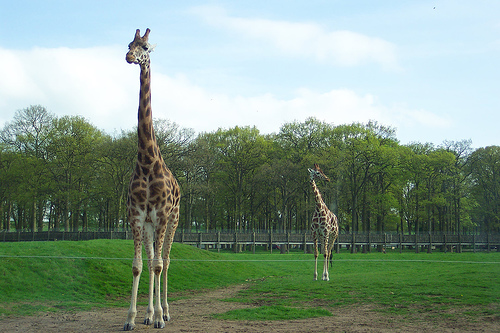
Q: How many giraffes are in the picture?
A: 2.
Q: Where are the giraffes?
A: On a field.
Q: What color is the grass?
A: Green.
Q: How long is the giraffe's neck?
A: Very long.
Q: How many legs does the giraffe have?
A: 4.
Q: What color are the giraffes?
A: Brown and tan.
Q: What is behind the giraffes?
A: Trees.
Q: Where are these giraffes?
A: In an enclosure.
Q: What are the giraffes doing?
A: Standing.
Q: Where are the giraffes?
A: In a park.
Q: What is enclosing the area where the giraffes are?
A: A fence.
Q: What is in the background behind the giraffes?
A: Trees.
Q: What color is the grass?
A: Green.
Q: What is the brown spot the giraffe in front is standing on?
A: Dirt patch.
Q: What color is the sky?
A: Blue and white.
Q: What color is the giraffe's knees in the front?
A: Brown.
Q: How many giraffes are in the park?
A: 2.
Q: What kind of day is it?
A: Sunny.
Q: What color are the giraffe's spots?
A: Brown and Tan.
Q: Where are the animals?
A: Grass field.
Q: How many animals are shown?
A: 2.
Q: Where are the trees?
A: Behind the fence.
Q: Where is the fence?
A: Edge of the field.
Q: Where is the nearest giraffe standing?
A: On dirt.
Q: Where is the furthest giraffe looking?
A: To the right.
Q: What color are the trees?
A: Green.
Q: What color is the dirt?
A: Brown.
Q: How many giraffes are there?
A: Two.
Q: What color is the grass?
A: Green.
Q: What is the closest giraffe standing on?
A: Dirt.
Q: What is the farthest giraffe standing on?
A: Grass.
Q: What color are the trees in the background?
A: Green.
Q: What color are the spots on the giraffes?
A: Brown.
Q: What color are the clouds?
A: White.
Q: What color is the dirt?
A: Brown.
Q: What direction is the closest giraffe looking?
A: Forward.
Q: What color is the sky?
A: Blue.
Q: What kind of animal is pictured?
A: Giraffe.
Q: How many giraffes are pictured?
A: Two.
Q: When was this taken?
A: Daytime.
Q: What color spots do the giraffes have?
A: Brown.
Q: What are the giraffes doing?
A: Walking.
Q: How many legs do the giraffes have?
A: Four.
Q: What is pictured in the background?
A: Trees.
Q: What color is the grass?
A: Green.